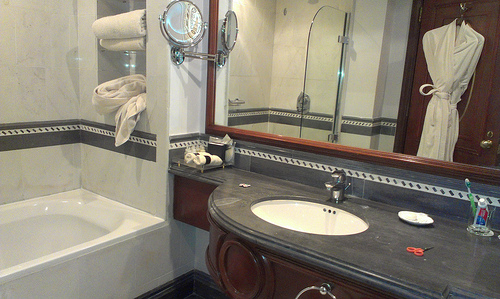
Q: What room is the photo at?
A: It is at the bathroom.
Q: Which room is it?
A: It is a bathroom.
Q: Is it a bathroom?
A: Yes, it is a bathroom.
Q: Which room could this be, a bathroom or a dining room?
A: It is a bathroom.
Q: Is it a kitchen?
A: No, it is a bathroom.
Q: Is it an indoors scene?
A: Yes, it is indoors.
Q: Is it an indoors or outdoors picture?
A: It is indoors.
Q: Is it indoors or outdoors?
A: It is indoors.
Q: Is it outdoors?
A: No, it is indoors.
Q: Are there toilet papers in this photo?
A: No, there are no toilet papers.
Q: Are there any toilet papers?
A: No, there are no toilet papers.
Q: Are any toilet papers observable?
A: No, there are no toilet papers.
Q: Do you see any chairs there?
A: No, there are no chairs.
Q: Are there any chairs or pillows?
A: No, there are no chairs or pillows.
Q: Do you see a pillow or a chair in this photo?
A: No, there are no chairs or pillows.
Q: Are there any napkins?
A: No, there are no napkins.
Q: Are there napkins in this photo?
A: No, there are no napkins.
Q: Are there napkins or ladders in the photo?
A: No, there are no napkins or ladders.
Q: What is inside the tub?
A: The water is inside the tub.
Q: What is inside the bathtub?
A: The water is inside the tub.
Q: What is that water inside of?
A: The water is inside the bathtub.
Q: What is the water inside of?
A: The water is inside the bathtub.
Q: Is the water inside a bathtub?
A: Yes, the water is inside a bathtub.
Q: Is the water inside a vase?
A: No, the water is inside a bathtub.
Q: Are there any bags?
A: No, there are no bags.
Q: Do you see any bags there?
A: No, there are no bags.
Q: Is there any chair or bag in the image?
A: No, there are no bags or chairs.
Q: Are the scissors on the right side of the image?
A: Yes, the scissors are on the right of the image.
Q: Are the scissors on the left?
A: No, the scissors are on the right of the image.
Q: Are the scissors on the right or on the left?
A: The scissors are on the right of the image.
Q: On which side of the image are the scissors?
A: The scissors are on the right of the image.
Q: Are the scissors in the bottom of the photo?
A: Yes, the scissors are in the bottom of the image.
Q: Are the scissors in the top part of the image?
A: No, the scissors are in the bottom of the image.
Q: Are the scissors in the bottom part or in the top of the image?
A: The scissors are in the bottom of the image.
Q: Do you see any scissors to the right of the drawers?
A: Yes, there are scissors to the right of the drawers.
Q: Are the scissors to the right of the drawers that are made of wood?
A: Yes, the scissors are to the right of the drawers.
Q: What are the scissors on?
A: The scissors are on the counter top.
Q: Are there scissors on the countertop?
A: Yes, there are scissors on the countertop.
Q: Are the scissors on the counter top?
A: Yes, the scissors are on the counter top.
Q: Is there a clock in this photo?
A: No, there are no clocks.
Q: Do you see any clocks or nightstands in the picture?
A: No, there are no clocks or nightstands.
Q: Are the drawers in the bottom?
A: Yes, the drawers are in the bottom of the image.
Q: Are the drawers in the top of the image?
A: No, the drawers are in the bottom of the image.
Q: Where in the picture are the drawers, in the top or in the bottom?
A: The drawers are in the bottom of the image.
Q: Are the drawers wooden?
A: Yes, the drawers are wooden.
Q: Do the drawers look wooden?
A: Yes, the drawers are wooden.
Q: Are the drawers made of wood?
A: Yes, the drawers are made of wood.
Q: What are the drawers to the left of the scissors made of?
A: The drawers are made of wood.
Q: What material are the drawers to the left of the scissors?
A: The drawers are made of wood.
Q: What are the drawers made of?
A: The drawers are made of wood.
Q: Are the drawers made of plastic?
A: No, the drawers are made of wood.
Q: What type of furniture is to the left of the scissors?
A: The pieces of furniture are drawers.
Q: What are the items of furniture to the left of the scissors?
A: The pieces of furniture are drawers.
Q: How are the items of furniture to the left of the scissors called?
A: The pieces of furniture are drawers.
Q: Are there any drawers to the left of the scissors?
A: Yes, there are drawers to the left of the scissors.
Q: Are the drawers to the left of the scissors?
A: Yes, the drawers are to the left of the scissors.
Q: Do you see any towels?
A: Yes, there is a towel.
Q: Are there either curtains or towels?
A: Yes, there is a towel.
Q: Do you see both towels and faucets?
A: Yes, there are both a towel and a faucet.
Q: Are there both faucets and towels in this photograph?
A: Yes, there are both a towel and a faucet.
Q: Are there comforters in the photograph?
A: No, there are no comforters.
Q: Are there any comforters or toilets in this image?
A: No, there are no comforters or toilets.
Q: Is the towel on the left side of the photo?
A: Yes, the towel is on the left of the image.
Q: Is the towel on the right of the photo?
A: No, the towel is on the left of the image.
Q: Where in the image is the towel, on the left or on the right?
A: The towel is on the left of the image.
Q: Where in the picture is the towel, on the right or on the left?
A: The towel is on the left of the image.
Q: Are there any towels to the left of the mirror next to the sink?
A: Yes, there is a towel to the left of the mirror.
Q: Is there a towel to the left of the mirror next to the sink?
A: Yes, there is a towel to the left of the mirror.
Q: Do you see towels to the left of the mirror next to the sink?
A: Yes, there is a towel to the left of the mirror.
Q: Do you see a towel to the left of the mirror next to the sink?
A: Yes, there is a towel to the left of the mirror.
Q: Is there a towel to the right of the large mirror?
A: No, the towel is to the left of the mirror.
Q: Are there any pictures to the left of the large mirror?
A: No, there is a towel to the left of the mirror.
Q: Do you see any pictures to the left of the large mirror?
A: No, there is a towel to the left of the mirror.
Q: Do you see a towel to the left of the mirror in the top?
A: Yes, there is a towel to the left of the mirror.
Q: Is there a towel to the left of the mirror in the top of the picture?
A: Yes, there is a towel to the left of the mirror.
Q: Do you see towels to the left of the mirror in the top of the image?
A: Yes, there is a towel to the left of the mirror.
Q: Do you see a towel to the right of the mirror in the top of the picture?
A: No, the towel is to the left of the mirror.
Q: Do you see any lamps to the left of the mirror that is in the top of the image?
A: No, there is a towel to the left of the mirror.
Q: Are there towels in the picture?
A: Yes, there is a towel.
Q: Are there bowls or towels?
A: Yes, there is a towel.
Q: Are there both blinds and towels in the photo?
A: No, there is a towel but no blinds.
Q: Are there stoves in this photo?
A: No, there are no stoves.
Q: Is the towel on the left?
A: Yes, the towel is on the left of the image.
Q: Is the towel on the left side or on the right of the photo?
A: The towel is on the left of the image.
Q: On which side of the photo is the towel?
A: The towel is on the left of the image.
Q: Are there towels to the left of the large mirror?
A: Yes, there is a towel to the left of the mirror.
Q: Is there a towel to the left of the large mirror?
A: Yes, there is a towel to the left of the mirror.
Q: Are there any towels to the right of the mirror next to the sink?
A: No, the towel is to the left of the mirror.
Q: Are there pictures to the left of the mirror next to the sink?
A: No, there is a towel to the left of the mirror.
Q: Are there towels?
A: Yes, there is a towel.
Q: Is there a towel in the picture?
A: Yes, there is a towel.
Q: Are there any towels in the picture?
A: Yes, there is a towel.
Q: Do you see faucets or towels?
A: Yes, there is a towel.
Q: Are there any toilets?
A: No, there are no toilets.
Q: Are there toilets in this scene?
A: No, there are no toilets.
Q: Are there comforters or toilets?
A: No, there are no toilets or comforters.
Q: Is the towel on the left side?
A: Yes, the towel is on the left of the image.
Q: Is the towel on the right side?
A: No, the towel is on the left of the image.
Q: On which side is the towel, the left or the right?
A: The towel is on the left of the image.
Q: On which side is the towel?
A: The towel is on the left of the image.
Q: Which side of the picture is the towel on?
A: The towel is on the left of the image.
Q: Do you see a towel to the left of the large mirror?
A: Yes, there is a towel to the left of the mirror.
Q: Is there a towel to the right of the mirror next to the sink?
A: No, the towel is to the left of the mirror.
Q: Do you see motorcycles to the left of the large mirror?
A: No, there is a towel to the left of the mirror.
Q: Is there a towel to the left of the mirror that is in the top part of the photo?
A: Yes, there is a towel to the left of the mirror.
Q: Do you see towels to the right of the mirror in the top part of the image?
A: No, the towel is to the left of the mirror.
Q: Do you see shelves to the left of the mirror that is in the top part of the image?
A: No, there is a towel to the left of the mirror.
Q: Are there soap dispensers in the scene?
A: No, there are no soap dispensers.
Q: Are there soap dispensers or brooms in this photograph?
A: No, there are no soap dispensers or brooms.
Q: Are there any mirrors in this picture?
A: Yes, there is a mirror.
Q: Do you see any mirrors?
A: Yes, there is a mirror.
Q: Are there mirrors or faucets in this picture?
A: Yes, there is a mirror.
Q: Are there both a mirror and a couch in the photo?
A: No, there is a mirror but no couches.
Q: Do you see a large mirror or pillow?
A: Yes, there is a large mirror.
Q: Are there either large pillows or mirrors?
A: Yes, there is a large mirror.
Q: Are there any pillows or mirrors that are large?
A: Yes, the mirror is large.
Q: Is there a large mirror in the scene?
A: Yes, there is a large mirror.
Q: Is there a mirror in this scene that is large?
A: Yes, there is a mirror that is large.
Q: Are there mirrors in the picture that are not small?
A: Yes, there is a large mirror.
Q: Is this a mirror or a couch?
A: This is a mirror.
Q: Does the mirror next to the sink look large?
A: Yes, the mirror is large.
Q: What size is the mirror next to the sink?
A: The mirror is large.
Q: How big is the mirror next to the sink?
A: The mirror is large.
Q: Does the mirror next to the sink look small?
A: No, the mirror is large.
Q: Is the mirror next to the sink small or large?
A: The mirror is large.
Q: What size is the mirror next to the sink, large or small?
A: The mirror is large.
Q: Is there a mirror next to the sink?
A: Yes, there is a mirror next to the sink.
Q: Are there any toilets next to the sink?
A: No, there is a mirror next to the sink.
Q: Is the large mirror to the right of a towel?
A: Yes, the mirror is to the right of a towel.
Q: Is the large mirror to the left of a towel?
A: No, the mirror is to the right of a towel.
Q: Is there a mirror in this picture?
A: Yes, there is a mirror.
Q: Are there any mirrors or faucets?
A: Yes, there is a mirror.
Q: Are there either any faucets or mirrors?
A: Yes, there is a mirror.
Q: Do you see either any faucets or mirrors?
A: Yes, there is a mirror.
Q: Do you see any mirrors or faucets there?
A: Yes, there is a mirror.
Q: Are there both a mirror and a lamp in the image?
A: No, there is a mirror but no lamps.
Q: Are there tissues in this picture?
A: No, there are no tissues.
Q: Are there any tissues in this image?
A: No, there are no tissues.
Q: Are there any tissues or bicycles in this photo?
A: No, there are no tissues or bicycles.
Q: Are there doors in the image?
A: Yes, there is a door.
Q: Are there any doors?
A: Yes, there is a door.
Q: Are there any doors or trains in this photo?
A: Yes, there is a door.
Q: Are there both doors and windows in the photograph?
A: No, there is a door but no windows.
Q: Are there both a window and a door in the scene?
A: No, there is a door but no windows.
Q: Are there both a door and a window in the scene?
A: No, there is a door but no windows.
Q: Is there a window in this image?
A: No, there are no windows.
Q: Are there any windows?
A: No, there are no windows.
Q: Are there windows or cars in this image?
A: No, there are no windows or cars.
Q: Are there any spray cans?
A: No, there are no spray cans.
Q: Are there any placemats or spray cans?
A: No, there are no spray cans or placemats.